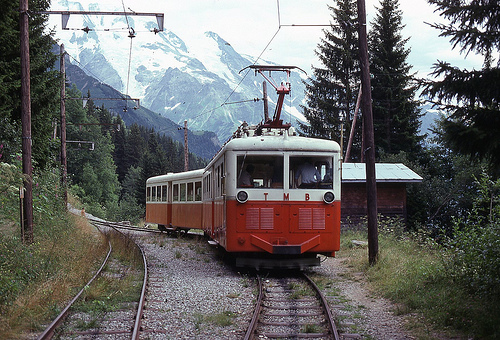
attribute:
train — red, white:
[184, 130, 347, 261]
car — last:
[142, 172, 172, 225]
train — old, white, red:
[152, 130, 349, 256]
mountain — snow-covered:
[150, 46, 240, 95]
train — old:
[199, 138, 339, 263]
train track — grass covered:
[82, 259, 148, 332]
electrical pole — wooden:
[2, 15, 51, 251]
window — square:
[138, 181, 171, 204]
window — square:
[148, 181, 171, 207]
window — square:
[166, 174, 196, 207]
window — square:
[183, 180, 203, 207]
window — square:
[232, 149, 291, 189]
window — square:
[291, 156, 338, 192]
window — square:
[200, 167, 223, 208]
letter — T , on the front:
[255, 186, 274, 205]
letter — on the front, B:
[282, 183, 329, 211]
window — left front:
[236, 153, 292, 203]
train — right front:
[153, 125, 387, 268]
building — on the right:
[335, 135, 445, 215]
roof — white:
[344, 152, 422, 187]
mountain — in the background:
[40, 0, 494, 219]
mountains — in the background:
[69, 13, 466, 233]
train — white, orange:
[121, 121, 387, 291]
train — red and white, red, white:
[139, 118, 341, 272]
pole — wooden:
[353, 0, 380, 266]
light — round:
[322, 190, 334, 203]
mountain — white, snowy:
[34, 0, 450, 160]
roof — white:
[340, 162, 422, 182]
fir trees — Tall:
[3, 3, 213, 240]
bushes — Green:
[374, 173, 497, 336]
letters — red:
[261, 190, 311, 202]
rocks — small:
[110, 229, 349, 339]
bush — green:
[415, 172, 496, 298]